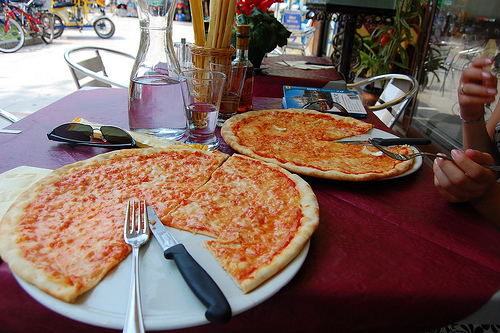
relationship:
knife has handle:
[142, 201, 235, 324] [162, 241, 235, 328]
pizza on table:
[2, 142, 330, 309] [2, 79, 500, 332]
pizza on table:
[214, 103, 423, 185] [2, 79, 500, 332]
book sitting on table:
[277, 78, 371, 121] [2, 79, 500, 332]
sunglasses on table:
[45, 120, 141, 154] [2, 79, 500, 332]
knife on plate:
[142, 201, 235, 324] [6, 229, 318, 331]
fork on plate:
[122, 195, 154, 333] [6, 229, 318, 331]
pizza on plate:
[2, 142, 330, 309] [6, 229, 318, 331]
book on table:
[277, 78, 371, 121] [2, 79, 500, 332]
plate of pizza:
[6, 229, 318, 331] [2, 142, 330, 309]